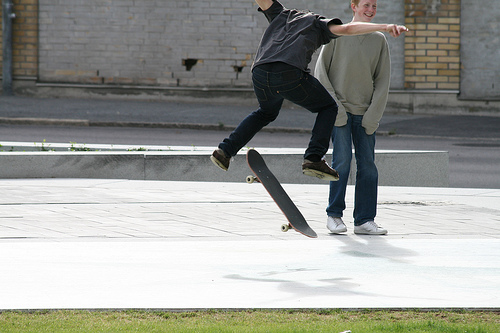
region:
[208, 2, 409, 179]
the boy is in the air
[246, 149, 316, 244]
the skateboard is in the air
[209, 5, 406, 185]
boy is going skateboarding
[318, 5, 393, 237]
the other boy is standing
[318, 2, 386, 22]
the other boy is grinning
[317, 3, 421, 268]
the standing boy has a shadow by his feet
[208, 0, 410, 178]
the skateboarder appears headless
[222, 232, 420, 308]
two shadows are on the ground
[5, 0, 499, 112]
a brick wall is behind the boys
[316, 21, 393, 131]
the boy is wearing a grey shirt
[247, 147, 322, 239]
a black skateboard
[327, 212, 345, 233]
the shoe of a boy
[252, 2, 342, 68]
a boy's black short sleeve shirt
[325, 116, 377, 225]
a boy's blue jean pants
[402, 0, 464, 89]
a light brown brick wall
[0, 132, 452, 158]
a white street marking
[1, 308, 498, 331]
a portion of green grass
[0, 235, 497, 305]
a concrete sidewalk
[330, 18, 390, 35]
the arm of a boy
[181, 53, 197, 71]
a section of missing brick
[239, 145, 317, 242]
THE BOY IS SKATEBOARDING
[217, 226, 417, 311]
THE BOYS ARE CASTING SHADOWS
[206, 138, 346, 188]
THE BOY IS WEARING BLACK SHOES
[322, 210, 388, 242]
THE BOY IS WEARING WHITE SHOES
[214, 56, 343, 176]
THE BOY IS WEARING BLACK JEANS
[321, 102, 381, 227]
THE BOY IS WEARING BLUE JEANS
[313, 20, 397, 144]
THE BOY IS WEARING A GREY SWEATER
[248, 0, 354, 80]
THE BOY IS WEARING A BLACK T-SHIRT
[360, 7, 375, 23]
THE BOY IS SMILING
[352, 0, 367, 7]
THE BOY HAS SHORT HAIR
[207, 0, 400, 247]
a skateboarder performing trick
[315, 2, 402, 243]
young man standing on sidewalk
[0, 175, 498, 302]
a white paved sidewalk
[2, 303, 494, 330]
a patch of green grass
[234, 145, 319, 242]
a black skateboard in air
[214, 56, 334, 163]
a pair of black jeans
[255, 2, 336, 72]
a black t-shirt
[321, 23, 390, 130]
long sleeved grey sweater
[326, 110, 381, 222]
a pair of men's blue jeans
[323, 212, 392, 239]
a pair of white tennis shoes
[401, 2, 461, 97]
brick column on wall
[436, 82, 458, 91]
small tan brick on column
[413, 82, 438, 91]
small tan brick on column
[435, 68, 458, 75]
small tan brick on column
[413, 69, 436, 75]
small tan brick on column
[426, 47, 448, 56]
small tan brick on column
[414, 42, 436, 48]
small tan brick on column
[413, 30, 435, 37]
small tan brick on column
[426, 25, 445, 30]
small tan brick on column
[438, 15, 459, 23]
small tan brick on column